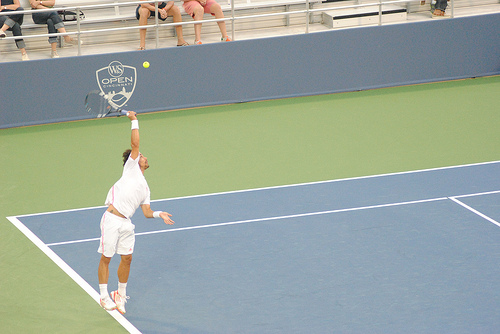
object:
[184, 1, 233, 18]
shorts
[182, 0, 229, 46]
person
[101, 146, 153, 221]
shirt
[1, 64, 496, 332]
court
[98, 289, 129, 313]
shoes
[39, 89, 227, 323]
player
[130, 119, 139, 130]
wristband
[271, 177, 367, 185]
line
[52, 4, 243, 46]
bleachers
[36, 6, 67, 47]
legs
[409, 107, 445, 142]
ground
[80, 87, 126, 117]
raquet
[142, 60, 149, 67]
ball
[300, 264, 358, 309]
court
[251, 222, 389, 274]
court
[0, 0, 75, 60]
women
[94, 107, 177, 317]
he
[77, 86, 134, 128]
tennis racket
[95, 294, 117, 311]
shoe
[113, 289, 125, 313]
shoe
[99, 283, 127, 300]
socks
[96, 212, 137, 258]
shorts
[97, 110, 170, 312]
person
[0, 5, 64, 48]
jeans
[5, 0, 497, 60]
bleachers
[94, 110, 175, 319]
tennis player